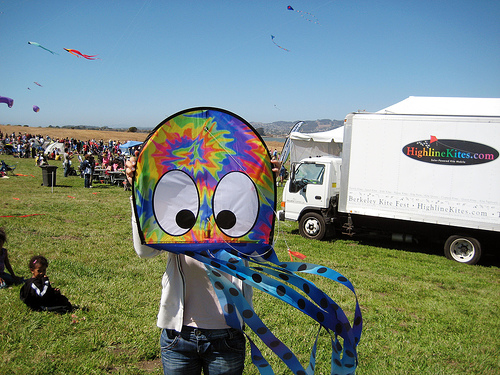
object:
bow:
[30, 258, 39, 265]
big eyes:
[147, 169, 261, 239]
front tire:
[297, 209, 329, 241]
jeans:
[159, 325, 248, 374]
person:
[122, 146, 281, 373]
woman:
[125, 142, 250, 373]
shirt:
[130, 192, 252, 329]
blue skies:
[356, 6, 441, 57]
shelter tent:
[289, 127, 344, 170]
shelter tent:
[376, 95, 498, 113]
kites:
[0, 2, 297, 120]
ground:
[266, 65, 304, 104]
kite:
[260, 31, 292, 57]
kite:
[58, 39, 100, 66]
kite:
[18, 32, 58, 59]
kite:
[277, 3, 317, 19]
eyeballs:
[148, 163, 263, 245]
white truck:
[283, 114, 498, 262]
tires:
[300, 194, 496, 268]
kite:
[128, 106, 363, 373]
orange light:
[279, 199, 289, 211]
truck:
[282, 110, 494, 258]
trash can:
[31, 161, 61, 183]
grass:
[0, 153, 498, 371]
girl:
[18, 252, 74, 313]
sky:
[8, 11, 486, 119]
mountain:
[253, 18, 429, 99]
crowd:
[14, 133, 115, 179]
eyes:
[154, 166, 261, 237]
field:
[18, 120, 139, 139]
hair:
[36, 249, 50, 265]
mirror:
[284, 162, 300, 192]